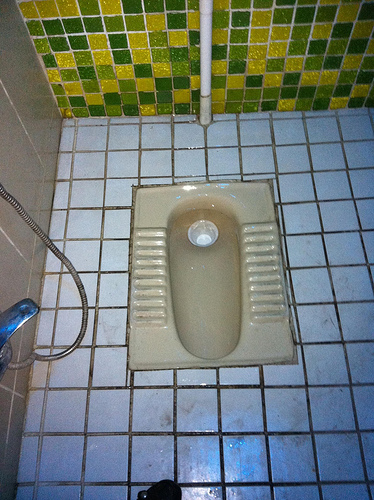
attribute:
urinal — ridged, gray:
[131, 177, 295, 372]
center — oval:
[185, 213, 215, 253]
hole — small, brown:
[185, 219, 220, 248]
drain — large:
[133, 179, 295, 366]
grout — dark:
[21, 427, 373, 433]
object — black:
[134, 477, 195, 497]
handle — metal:
[0, 296, 39, 352]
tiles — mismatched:
[61, 1, 197, 115]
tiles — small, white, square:
[16, 108, 371, 498]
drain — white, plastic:
[188, 217, 219, 249]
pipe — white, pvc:
[198, 0, 214, 125]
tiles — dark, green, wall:
[40, 14, 92, 54]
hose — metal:
[0, 176, 94, 377]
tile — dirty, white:
[134, 387, 265, 481]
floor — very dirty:
[17, 110, 372, 497]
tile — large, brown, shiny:
[103, 149, 140, 176]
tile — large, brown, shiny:
[140, 149, 174, 176]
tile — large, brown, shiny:
[171, 147, 206, 177]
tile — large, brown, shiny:
[205, 146, 240, 175]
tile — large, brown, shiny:
[240, 145, 277, 173]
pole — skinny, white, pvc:
[196, 0, 213, 125]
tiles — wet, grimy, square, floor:
[287, 151, 339, 192]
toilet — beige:
[121, 178, 299, 373]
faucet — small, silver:
[1, 295, 43, 373]